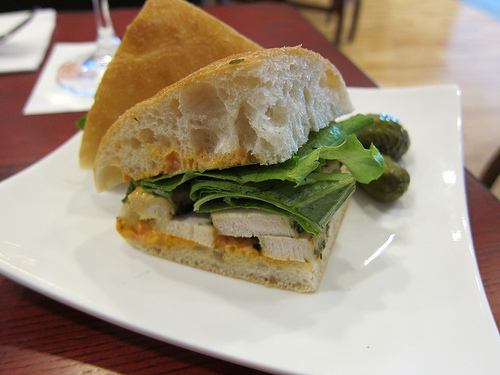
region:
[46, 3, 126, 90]
the bottom of a wine glass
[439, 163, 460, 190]
light reflecting on the plate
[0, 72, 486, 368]
a geometrically shaped plate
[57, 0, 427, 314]
a panini on a white plate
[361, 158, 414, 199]
a dark green caper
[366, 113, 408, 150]
a sour caper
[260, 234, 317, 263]
a moist chunk of white meat chicken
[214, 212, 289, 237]
a moist chunk of white meat chicken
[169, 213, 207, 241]
a moist chunk of white meat chicken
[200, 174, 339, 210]
crispy green lettuce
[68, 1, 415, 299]
Sandwich cut in half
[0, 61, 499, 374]
Small square white plate with sandwich on top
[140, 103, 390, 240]
Green lettuce topping on sandwich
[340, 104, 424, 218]
Green pickles on the side of the plate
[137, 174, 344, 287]
White pieces of meat in the sandwich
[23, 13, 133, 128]
White napkin on the table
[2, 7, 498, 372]
Plate and glass on the red table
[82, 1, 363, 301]
Close up of sandwich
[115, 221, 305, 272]
Yellow sauce on the bread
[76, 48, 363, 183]
Brown and white piece of bread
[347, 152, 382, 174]
lettuce on the sandwich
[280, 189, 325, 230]
lettuce on the sandwich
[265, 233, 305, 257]
meat on the sandiwch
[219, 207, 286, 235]
meat on the sandwich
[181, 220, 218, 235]
meat on the sandwich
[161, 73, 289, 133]
bread on the sandwich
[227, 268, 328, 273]
bread on the sandwich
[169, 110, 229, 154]
bread on the sandwich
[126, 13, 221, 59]
bread on the sandwich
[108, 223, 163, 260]
bread on the sandwich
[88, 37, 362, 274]
that is a sandwitch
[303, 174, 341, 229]
a peace of letuce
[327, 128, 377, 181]
a peace of letuce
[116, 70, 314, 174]
that is a peace of bread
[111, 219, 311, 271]
that is a peace of bread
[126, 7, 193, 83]
that is a peace of bread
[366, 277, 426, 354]
that is a plate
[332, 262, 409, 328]
that plate is flat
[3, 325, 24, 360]
that is a peace of bread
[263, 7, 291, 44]
that is the table